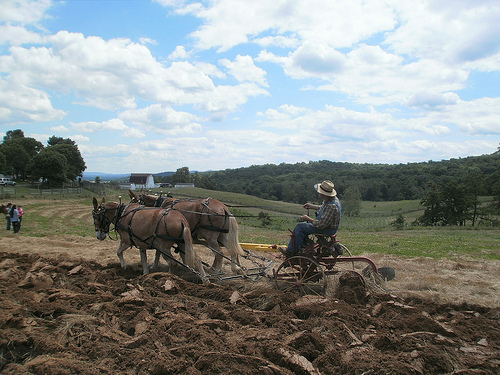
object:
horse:
[128, 189, 248, 273]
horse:
[91, 196, 207, 274]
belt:
[319, 227, 338, 231]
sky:
[0, 0, 500, 174]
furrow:
[0, 252, 84, 272]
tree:
[0, 129, 42, 185]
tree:
[47, 136, 87, 186]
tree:
[341, 186, 364, 218]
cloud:
[0, 1, 498, 121]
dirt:
[0, 252, 497, 372]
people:
[9, 205, 19, 234]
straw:
[417, 256, 495, 307]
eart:
[166, 354, 200, 369]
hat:
[313, 180, 337, 197]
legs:
[116, 242, 131, 264]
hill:
[157, 149, 500, 203]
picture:
[0, 0, 500, 369]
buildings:
[129, 173, 154, 188]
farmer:
[278, 181, 344, 256]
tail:
[181, 219, 195, 265]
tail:
[224, 207, 244, 256]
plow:
[332, 268, 370, 299]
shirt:
[307, 198, 341, 235]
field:
[6, 250, 499, 373]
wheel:
[273, 256, 329, 295]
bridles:
[107, 232, 119, 241]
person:
[4, 201, 11, 230]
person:
[17, 205, 25, 230]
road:
[3, 233, 495, 305]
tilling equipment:
[253, 222, 383, 298]